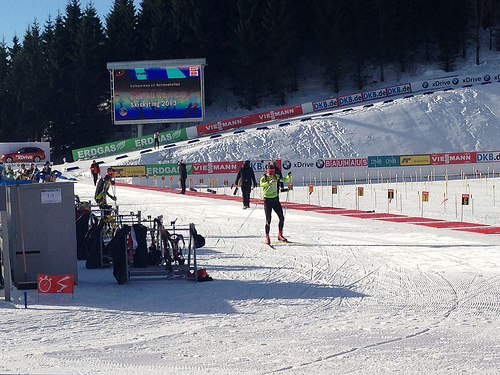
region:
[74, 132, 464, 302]
skiers on ski course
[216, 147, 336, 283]
skier wearing red boots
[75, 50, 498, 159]
ski path on hill of snow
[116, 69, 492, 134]
barrier between ski slope and woods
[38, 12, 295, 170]
evergreen trees in snow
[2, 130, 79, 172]
red car parked by white wall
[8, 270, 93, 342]
short red and white sign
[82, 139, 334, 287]
racks with gear on sidelines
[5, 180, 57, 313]
broom with long handle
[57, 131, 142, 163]
green and white advertisement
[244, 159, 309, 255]
person on skis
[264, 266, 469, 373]
thin track in the snow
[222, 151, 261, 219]
person wearing all black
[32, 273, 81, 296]
red and white sign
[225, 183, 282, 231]
thin ski pole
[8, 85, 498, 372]
grond is covered in snow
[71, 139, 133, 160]
white and green advertisement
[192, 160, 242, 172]
white writing on a red background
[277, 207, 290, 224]
knee is bent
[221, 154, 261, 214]
person walking on the snow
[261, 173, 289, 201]
The green shirt the skier is wearing.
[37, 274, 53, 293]
The image of a clock on the red sign on the left.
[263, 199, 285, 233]
The black pants the skier is wearing.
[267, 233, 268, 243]
The left red boot the skier is wearing.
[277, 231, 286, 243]
The right red boot of the skier.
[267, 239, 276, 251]
The left ski on the skier's foot.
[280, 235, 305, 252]
The right ski on the skier's foot.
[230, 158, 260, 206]
The person behind the skier dressed in all black.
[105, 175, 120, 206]
The skier on the right holding a crutch.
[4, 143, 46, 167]
The red car in the background.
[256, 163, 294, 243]
A man in a yellow top and black pants skiing.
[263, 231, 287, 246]
Red boots that hook onto skiis on the man skiing.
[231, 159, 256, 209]
A person in all black walking away.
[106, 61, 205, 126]
A large grey framed billboard with a lot of blue and the year 2013.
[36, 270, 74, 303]
A red sign with a clock and lightning bolt on it.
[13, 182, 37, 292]
A long brown handled black bottom push broom.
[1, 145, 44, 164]
A red two door car with white writing on the door.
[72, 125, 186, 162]
A green banner that says ERDGAS that is the longest banner.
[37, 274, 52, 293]
A white stopwatch on a red sign.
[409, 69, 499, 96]
A long white banner on the top of the hill that says xDrive twice.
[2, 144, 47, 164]
A red vehicle on display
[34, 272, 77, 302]
A small red sign in the snow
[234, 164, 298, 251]
A cross country skier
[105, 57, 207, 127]
A large digital display board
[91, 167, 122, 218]
A skier standing in the snow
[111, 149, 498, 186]
A line of advertisements on the wall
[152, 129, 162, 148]
A cross country skier on the hill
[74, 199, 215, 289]
A series of racks in the snow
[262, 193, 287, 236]
Black pants on the skier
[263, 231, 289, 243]
Red boots on the skier